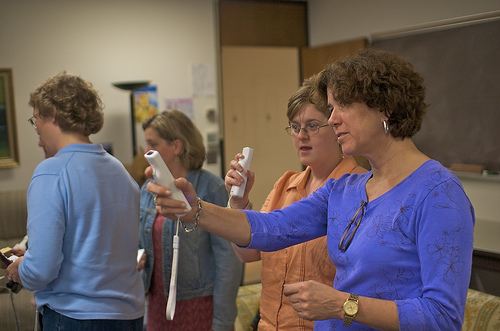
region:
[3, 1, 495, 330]
four people in a room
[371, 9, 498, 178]
empty blackboard on wall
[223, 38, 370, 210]
open door of room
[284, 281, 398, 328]
watch on woman's arm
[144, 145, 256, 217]
game controls in hands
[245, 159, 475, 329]
glasses hanging on shirt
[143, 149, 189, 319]
game control with loop handle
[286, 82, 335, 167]
glasses on woman's face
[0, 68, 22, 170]
edge of picture frame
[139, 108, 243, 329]
woman wearing jean jacket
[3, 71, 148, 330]
Woman wearing light blue sweater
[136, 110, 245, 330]
Woman wearing jean jacket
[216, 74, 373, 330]
Woman holding a Wii remote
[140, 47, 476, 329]
Woman holding a Wii remote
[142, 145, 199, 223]
White Wii remote in hand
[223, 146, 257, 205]
White Wii remote in hand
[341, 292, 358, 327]
Gold watch on wrist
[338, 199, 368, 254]
Pair of glasses on sweater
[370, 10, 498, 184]
Chalkboard on the wall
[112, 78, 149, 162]
Black floor lamp against wall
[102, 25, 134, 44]
Small part of the white wall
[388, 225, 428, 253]
Blue and brown shirt of the woman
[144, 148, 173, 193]
White Wii remote in the woman's hands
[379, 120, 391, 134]
Silver earring on woman's ear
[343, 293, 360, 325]
Golden watch on woman's hands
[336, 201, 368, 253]
Glasses on woman's shirt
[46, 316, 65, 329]
Small part of the elderly woman's jeans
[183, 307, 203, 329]
Small part of woman's red dress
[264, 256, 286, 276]
Orange shirt of the second woman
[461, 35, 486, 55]
Brown board i n the background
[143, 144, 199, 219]
one Caucasian hand holding video game remote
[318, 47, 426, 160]
woman with short dark curly hair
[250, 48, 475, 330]
woman wearing long sleeved blue shirt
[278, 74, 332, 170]
woman wearing thin wire framed glasses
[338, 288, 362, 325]
one round faced wristwatch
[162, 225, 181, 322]
one white Ninetendo Wii remote wrist strap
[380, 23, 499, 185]
one rectangular shaped blackboard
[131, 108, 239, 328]
one woman wearing blue denim jacket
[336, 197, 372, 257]
dark glasses hanging from shirt front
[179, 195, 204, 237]
chunky metal bracelet on right wrist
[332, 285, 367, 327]
A watch around a wrist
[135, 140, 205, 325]
White game controller in a hand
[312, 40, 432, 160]
Woman has short brown hair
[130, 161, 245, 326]
A blue jean jacket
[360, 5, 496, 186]
A chalkboard on the wall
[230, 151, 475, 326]
Blue sweater with glasses on it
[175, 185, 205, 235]
Bracelet around a wrist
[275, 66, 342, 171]
Woman is wearing glasses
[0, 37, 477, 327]
Four women playing a video game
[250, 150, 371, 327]
An orange button down shirt